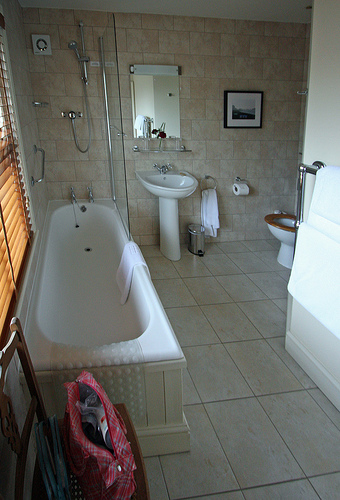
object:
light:
[129, 65, 135, 74]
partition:
[99, 12, 131, 240]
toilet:
[264, 214, 298, 270]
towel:
[200, 186, 220, 238]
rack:
[293, 160, 326, 265]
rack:
[200, 175, 217, 191]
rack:
[31, 144, 45, 186]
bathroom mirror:
[129, 64, 182, 140]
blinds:
[0, 29, 38, 349]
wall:
[211, 127, 276, 165]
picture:
[223, 90, 263, 128]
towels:
[286, 164, 340, 329]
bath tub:
[19, 197, 191, 457]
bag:
[61, 370, 138, 499]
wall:
[19, 9, 309, 246]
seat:
[264, 213, 297, 231]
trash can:
[187, 223, 206, 258]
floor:
[139, 237, 336, 498]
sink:
[135, 170, 199, 262]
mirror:
[129, 62, 182, 140]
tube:
[97, 405, 114, 450]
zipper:
[76, 378, 118, 461]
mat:
[49, 337, 147, 428]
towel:
[115, 240, 151, 306]